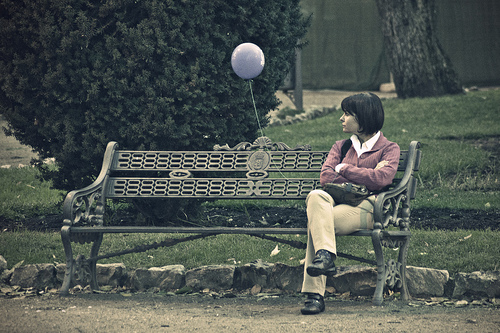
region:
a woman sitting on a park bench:
[300, 92, 401, 313]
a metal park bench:
[54, 141, 419, 306]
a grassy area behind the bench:
[1, 92, 499, 272]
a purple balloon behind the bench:
[231, 41, 263, 79]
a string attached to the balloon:
[248, 79, 292, 180]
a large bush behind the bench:
[0, 0, 312, 220]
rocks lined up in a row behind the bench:
[2, 257, 498, 296]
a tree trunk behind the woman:
[377, 0, 463, 99]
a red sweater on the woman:
[322, 133, 399, 189]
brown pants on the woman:
[300, 186, 386, 296]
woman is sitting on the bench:
[67, 57, 422, 320]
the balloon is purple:
[195, 23, 311, 191]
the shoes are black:
[281, 225, 356, 320]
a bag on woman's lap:
[291, 105, 388, 251]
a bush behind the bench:
[31, 14, 303, 309]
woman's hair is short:
[329, 75, 390, 165]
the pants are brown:
[268, 152, 366, 317]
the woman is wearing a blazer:
[318, 127, 397, 225]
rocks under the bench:
[123, 260, 357, 304]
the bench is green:
[20, 140, 390, 264]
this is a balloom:
[210, 29, 320, 169]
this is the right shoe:
[308, 246, 340, 281]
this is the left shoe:
[291, 282, 333, 316]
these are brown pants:
[293, 181, 384, 300]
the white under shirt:
[336, 108, 388, 163]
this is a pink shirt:
[315, 126, 417, 210]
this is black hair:
[325, 84, 410, 140]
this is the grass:
[438, 101, 460, 121]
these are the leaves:
[75, 38, 177, 116]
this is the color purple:
[242, 57, 248, 60]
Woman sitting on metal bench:
[300, 90, 400, 317]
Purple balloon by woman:
[230, 41, 312, 208]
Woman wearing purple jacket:
[298, 92, 399, 314]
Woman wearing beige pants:
[298, 92, 401, 315]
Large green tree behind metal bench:
[0, 0, 312, 221]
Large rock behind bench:
[127, 261, 182, 291]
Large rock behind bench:
[186, 260, 236, 288]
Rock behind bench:
[231, 253, 271, 285]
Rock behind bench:
[330, 261, 376, 293]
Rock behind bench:
[97, 261, 129, 286]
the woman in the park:
[69, 47, 443, 315]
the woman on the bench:
[48, 120, 445, 316]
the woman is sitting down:
[41, 115, 432, 293]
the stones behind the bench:
[78, 255, 490, 305]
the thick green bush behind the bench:
[2, 5, 260, 151]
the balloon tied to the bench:
[206, 37, 303, 203]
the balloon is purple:
[193, 16, 270, 111]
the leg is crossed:
[282, 189, 374, 315]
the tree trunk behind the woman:
[387, 5, 461, 98]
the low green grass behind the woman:
[398, 97, 478, 156]